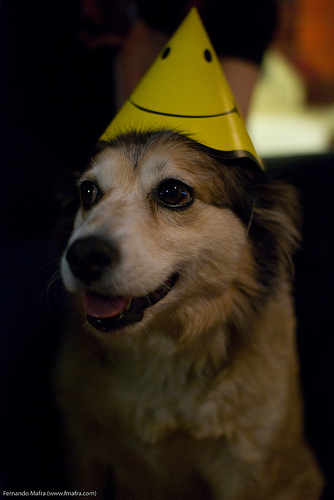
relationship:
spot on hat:
[195, 49, 212, 70] [92, 0, 263, 170]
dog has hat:
[43, 93, 329, 498] [92, 0, 263, 170]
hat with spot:
[92, 0, 263, 170] [199, 45, 214, 63]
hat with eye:
[92, 0, 263, 170] [160, 46, 170, 61]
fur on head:
[108, 119, 197, 171] [57, 128, 298, 332]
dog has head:
[43, 93, 329, 498] [57, 128, 298, 332]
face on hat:
[132, 42, 229, 123] [92, 0, 263, 170]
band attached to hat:
[242, 171, 256, 242] [92, 0, 263, 170]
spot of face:
[202, 48, 211, 64] [125, 42, 239, 122]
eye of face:
[158, 46, 172, 61] [125, 42, 239, 122]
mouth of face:
[128, 99, 243, 124] [125, 42, 239, 122]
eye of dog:
[152, 179, 196, 216] [48, 124, 323, 498]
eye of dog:
[77, 177, 102, 210] [48, 124, 323, 498]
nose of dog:
[61, 236, 118, 283] [48, 124, 323, 498]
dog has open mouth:
[43, 93, 329, 498] [83, 269, 180, 332]